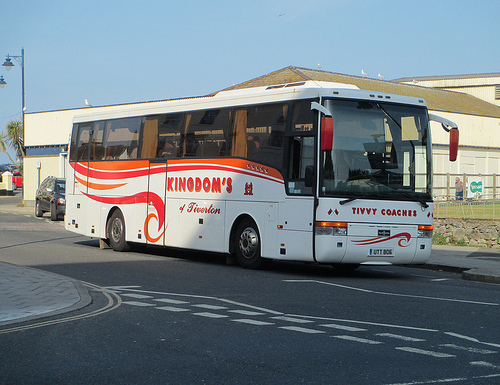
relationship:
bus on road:
[79, 103, 449, 276] [123, 255, 250, 357]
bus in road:
[79, 103, 449, 276] [123, 255, 250, 357]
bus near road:
[79, 103, 449, 276] [123, 255, 250, 357]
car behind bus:
[34, 177, 64, 218] [79, 103, 449, 276]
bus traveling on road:
[79, 103, 449, 276] [123, 255, 250, 357]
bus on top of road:
[79, 103, 449, 276] [123, 255, 250, 357]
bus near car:
[79, 103, 449, 276] [34, 177, 64, 218]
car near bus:
[34, 177, 64, 218] [79, 103, 449, 276]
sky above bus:
[143, 1, 260, 56] [79, 103, 449, 276]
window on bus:
[231, 100, 293, 176] [79, 103, 449, 276]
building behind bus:
[23, 65, 499, 202] [79, 103, 449, 276]